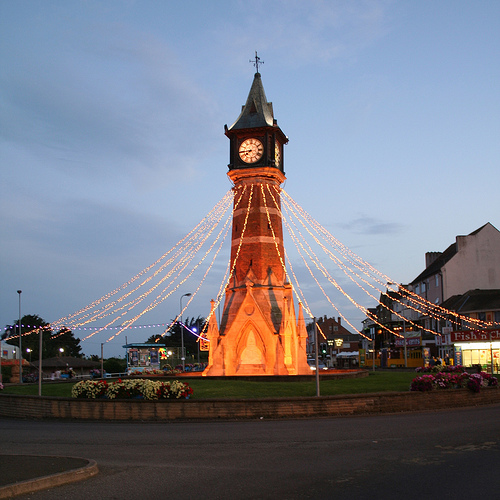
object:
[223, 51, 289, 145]
steeple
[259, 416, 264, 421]
gradd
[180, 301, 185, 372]
pole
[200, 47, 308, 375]
tower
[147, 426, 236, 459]
pavement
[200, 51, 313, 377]
pole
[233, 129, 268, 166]
clock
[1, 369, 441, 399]
grass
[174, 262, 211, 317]
cloud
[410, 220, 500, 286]
roof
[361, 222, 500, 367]
building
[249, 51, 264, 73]
weathervane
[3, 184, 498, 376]
lights